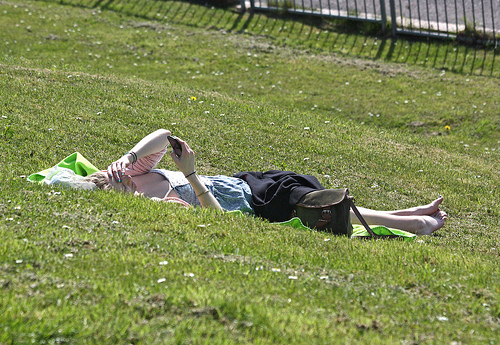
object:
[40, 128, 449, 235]
woman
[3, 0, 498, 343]
grass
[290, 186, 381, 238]
bag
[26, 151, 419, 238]
towel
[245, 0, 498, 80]
fence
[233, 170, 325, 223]
jacket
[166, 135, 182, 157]
cell phone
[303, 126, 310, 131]
flower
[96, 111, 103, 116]
flower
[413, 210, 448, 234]
feet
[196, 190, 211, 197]
bracelet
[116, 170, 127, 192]
eyes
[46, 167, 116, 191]
hair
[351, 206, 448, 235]
legs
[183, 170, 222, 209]
arm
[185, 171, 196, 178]
bracelet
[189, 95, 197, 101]
flower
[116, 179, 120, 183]
nai polish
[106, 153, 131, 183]
hand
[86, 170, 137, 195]
head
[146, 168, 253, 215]
tank top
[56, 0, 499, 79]
shadow